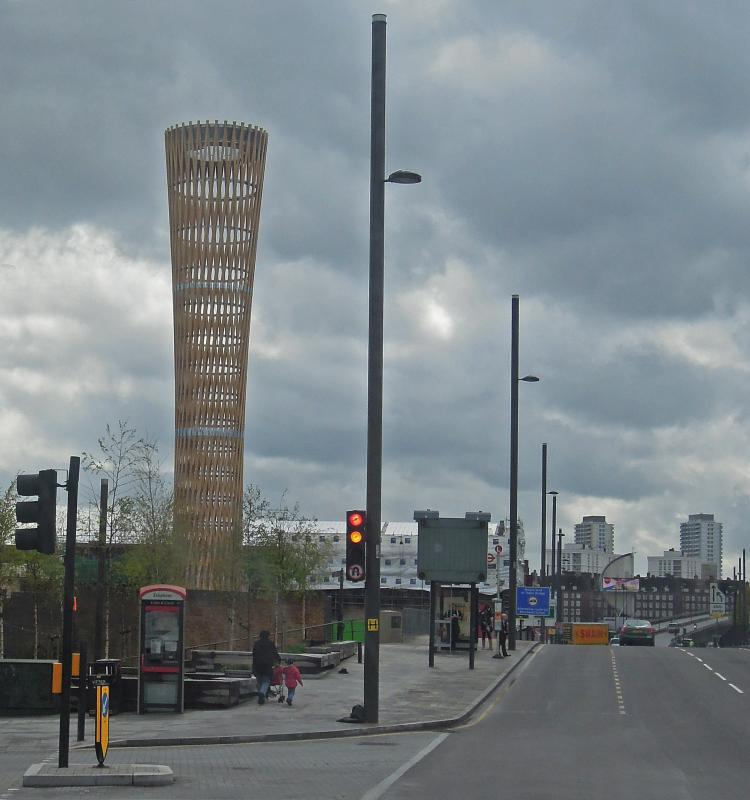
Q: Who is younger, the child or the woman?
A: The child is younger than the woman.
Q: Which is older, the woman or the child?
A: The woman is older than the child.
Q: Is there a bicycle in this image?
A: No, there are no bicycles.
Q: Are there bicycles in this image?
A: No, there are no bicycles.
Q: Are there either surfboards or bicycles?
A: No, there are no bicycles or surfboards.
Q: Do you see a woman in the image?
A: Yes, there is a woman.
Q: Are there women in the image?
A: Yes, there is a woman.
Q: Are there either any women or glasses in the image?
A: Yes, there is a woman.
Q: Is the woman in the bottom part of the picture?
A: Yes, the woman is in the bottom of the image.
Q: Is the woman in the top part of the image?
A: No, the woman is in the bottom of the image.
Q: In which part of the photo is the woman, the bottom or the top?
A: The woman is in the bottom of the image.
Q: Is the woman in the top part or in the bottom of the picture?
A: The woman is in the bottom of the image.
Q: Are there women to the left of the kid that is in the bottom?
A: Yes, there is a woman to the left of the child.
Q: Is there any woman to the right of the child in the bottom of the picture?
A: No, the woman is to the left of the child.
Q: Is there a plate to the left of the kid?
A: No, there is a woman to the left of the kid.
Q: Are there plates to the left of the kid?
A: No, there is a woman to the left of the kid.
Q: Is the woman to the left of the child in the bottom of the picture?
A: Yes, the woman is to the left of the kid.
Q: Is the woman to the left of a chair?
A: No, the woman is to the left of the kid.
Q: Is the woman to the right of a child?
A: No, the woman is to the left of a child.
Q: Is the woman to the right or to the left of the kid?
A: The woman is to the left of the kid.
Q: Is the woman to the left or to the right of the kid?
A: The woman is to the left of the kid.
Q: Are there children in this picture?
A: Yes, there is a child.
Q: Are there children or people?
A: Yes, there is a child.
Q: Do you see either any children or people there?
A: Yes, there is a child.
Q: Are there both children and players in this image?
A: No, there is a child but no players.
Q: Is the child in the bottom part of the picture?
A: Yes, the child is in the bottom of the image.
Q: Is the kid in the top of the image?
A: No, the kid is in the bottom of the image.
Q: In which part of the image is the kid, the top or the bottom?
A: The kid is in the bottom of the image.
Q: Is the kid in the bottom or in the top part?
A: The kid is in the bottom of the image.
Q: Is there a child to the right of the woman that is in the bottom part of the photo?
A: Yes, there is a child to the right of the woman.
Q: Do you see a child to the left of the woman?
A: No, the child is to the right of the woman.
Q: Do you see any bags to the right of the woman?
A: No, there is a child to the right of the woman.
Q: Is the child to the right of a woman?
A: Yes, the child is to the right of a woman.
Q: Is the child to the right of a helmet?
A: No, the child is to the right of a woman.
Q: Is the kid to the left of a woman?
A: No, the kid is to the right of a woman.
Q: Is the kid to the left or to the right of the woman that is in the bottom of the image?
A: The kid is to the right of the woman.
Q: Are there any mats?
A: No, there are no mats.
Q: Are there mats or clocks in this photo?
A: No, there are no mats or clocks.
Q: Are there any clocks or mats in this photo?
A: No, there are no mats or clocks.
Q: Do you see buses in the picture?
A: No, there are no buses.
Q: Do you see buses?
A: No, there are no buses.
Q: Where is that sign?
A: The sign is on the road.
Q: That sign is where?
A: The sign is on the road.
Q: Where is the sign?
A: The sign is on the road.